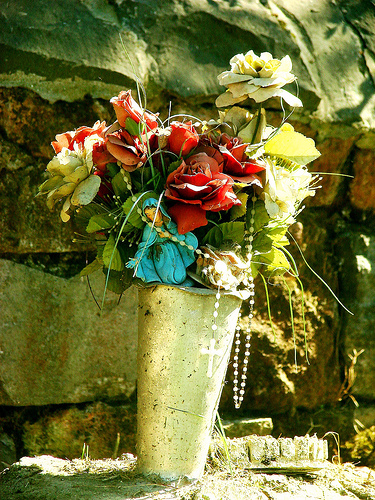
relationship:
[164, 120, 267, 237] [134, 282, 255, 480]
flower in vase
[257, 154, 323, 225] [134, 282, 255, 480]
flower in vase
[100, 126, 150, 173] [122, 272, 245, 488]
flower in vase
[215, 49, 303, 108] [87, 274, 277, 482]
flower in vase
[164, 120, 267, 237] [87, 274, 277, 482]
flower in vase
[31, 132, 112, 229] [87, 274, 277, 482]
flower in vase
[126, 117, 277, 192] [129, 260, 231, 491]
flower in vase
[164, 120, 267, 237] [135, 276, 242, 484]
flower in flower vase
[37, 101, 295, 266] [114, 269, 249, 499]
flower in vase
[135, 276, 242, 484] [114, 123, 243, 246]
flower vase of flowers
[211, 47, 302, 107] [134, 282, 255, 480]
flower displayed in vase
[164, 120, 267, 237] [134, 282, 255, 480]
flower displayed in vase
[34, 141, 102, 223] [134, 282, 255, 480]
flower displayed in vase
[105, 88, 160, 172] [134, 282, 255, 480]
flower displayed in vase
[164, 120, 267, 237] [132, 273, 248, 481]
flower in vase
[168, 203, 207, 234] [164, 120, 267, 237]
petal on flower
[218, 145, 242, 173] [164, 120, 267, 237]
petal on flower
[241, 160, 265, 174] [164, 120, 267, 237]
petal on flower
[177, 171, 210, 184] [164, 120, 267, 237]
petal on flower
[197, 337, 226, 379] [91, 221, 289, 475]
cross hanging from vase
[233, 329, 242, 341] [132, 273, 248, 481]
bead hanging from vase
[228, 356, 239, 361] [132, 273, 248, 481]
bead hanging from vase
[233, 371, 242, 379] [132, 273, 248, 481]
bead hanging from vase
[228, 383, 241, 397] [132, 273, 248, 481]
bead hanging from vase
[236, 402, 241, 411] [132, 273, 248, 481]
bead hanging from vase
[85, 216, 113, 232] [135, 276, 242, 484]
leaf in flower vase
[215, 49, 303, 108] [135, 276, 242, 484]
flower in flower vase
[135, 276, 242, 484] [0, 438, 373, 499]
flower vase on ground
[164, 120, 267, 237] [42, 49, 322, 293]
flower in group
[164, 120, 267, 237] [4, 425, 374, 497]
flower on ground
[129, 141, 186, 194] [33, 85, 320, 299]
hoops holds flowers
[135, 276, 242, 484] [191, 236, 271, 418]
flower vase with rosary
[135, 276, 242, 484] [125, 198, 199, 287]
flower vase with figurine